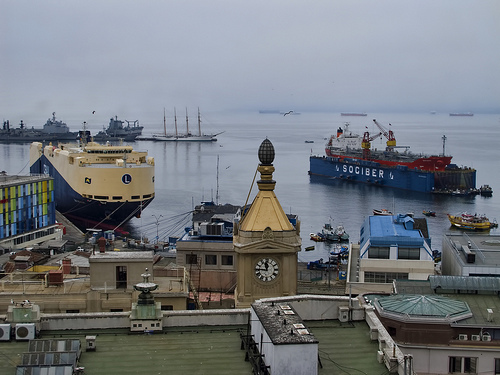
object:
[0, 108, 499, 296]
pier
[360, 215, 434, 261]
blue roof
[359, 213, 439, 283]
building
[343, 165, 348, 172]
letter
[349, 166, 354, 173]
letter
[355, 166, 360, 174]
letter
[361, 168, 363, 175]
letter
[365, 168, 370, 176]
letter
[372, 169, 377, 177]
letter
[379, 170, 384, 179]
letter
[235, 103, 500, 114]
land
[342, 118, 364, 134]
ground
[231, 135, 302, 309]
building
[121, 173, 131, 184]
blue logo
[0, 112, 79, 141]
boat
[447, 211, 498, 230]
boat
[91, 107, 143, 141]
boat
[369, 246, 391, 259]
window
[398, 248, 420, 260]
window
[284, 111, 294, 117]
bird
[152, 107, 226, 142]
boat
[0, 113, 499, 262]
ocean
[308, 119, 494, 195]
boat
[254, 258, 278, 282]
clock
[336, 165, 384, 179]
letters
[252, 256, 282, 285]
face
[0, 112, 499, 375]
port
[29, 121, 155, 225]
boat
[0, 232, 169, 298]
dock